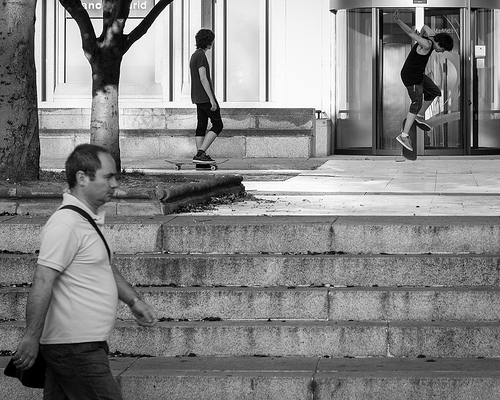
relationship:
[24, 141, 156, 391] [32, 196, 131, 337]
man in shirt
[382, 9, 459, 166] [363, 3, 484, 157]
boy in front of door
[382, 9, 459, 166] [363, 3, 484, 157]
boy jumping in front of door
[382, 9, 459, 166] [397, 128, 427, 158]
boy has foot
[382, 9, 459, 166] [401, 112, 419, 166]
boy has skateboard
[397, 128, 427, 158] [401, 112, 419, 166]
foot on skateboard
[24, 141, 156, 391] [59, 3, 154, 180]
man in front of tree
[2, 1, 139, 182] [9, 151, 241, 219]
trees in planter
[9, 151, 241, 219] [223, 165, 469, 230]
planter on sidewalk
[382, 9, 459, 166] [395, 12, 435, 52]
boy swinging arms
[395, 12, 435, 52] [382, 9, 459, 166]
arms behind boy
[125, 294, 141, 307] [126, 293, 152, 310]
watch on wrist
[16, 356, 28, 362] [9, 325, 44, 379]
ring on hand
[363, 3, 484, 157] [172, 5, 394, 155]
door into building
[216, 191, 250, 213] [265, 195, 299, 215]
leaves and dirt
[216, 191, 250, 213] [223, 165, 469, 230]
leaves on sidewalk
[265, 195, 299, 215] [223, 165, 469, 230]
dirt on sidewalk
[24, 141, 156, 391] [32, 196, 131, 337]
man wearing polo shirt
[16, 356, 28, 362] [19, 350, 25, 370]
ring on finger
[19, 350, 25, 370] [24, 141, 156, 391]
finger of man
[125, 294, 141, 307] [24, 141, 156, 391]
watch on man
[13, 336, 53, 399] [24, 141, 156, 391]
bag behind man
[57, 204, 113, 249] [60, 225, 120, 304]
strap across chest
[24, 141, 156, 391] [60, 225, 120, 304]
man has chest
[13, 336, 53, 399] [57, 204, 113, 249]
bag has strap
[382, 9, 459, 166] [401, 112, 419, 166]
boy jumping on skateboard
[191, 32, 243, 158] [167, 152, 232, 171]
boy standing on skateboard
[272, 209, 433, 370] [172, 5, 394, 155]
stairs leading to skateboarders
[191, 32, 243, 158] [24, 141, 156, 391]
teenager and man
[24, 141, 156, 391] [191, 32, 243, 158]
man and teenager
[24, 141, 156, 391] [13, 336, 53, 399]
man carrying bag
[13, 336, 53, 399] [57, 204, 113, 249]
bag on strap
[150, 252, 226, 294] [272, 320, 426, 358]
markings on stairs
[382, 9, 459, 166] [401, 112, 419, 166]
boy jumping with skateboard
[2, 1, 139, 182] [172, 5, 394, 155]
trees in front of building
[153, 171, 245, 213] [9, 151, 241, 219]
corners of planting area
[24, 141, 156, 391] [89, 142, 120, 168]
man with hairline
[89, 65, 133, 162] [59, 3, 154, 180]
trunk of tree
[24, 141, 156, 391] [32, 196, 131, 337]
man wearing shirt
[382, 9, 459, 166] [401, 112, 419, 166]
boy jumps with skateboard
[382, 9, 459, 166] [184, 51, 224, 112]
boy wearing t-shirt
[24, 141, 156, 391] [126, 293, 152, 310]
man wears band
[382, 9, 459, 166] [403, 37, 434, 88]
boy wears tank top